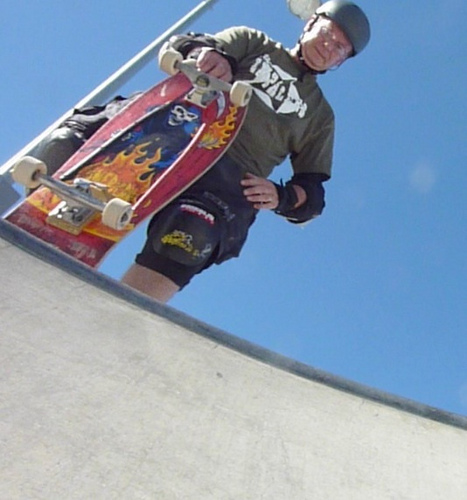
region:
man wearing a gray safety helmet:
[295, 0, 371, 75]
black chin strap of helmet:
[293, 12, 328, 72]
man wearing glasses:
[314, 23, 348, 59]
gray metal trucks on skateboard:
[176, 60, 230, 108]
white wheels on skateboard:
[229, 80, 252, 106]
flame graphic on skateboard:
[195, 102, 241, 150]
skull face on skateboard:
[167, 103, 198, 129]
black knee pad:
[149, 199, 224, 271]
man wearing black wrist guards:
[275, 178, 301, 214]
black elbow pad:
[290, 174, 327, 224]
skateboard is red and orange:
[33, 58, 242, 236]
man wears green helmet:
[313, 0, 367, 57]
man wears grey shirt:
[213, 19, 349, 201]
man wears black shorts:
[90, 77, 254, 297]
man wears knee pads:
[152, 181, 232, 279]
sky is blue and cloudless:
[342, 15, 466, 459]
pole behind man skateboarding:
[19, 1, 268, 149]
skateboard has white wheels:
[160, 48, 248, 118]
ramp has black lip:
[10, 216, 466, 410]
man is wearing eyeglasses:
[321, 12, 345, 75]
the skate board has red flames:
[95, 95, 241, 206]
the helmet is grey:
[329, 6, 379, 44]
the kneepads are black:
[171, 206, 233, 248]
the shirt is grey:
[251, 40, 335, 160]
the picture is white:
[257, 57, 318, 111]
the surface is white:
[53, 381, 240, 455]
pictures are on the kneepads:
[163, 227, 203, 249]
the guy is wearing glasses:
[300, 19, 358, 83]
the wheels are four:
[7, 55, 265, 235]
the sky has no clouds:
[379, 117, 427, 334]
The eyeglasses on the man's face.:
[318, 18, 351, 50]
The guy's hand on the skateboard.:
[194, 41, 237, 74]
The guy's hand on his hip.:
[244, 170, 278, 212]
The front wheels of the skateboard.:
[162, 48, 257, 110]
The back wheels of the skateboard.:
[19, 153, 143, 235]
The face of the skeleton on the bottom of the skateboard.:
[170, 99, 196, 123]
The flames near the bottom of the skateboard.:
[105, 136, 161, 201]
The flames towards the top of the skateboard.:
[203, 92, 236, 150]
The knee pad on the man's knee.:
[148, 189, 223, 261]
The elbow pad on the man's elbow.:
[295, 179, 330, 227]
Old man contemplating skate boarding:
[7, 4, 371, 318]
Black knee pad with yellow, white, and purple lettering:
[149, 196, 222, 269]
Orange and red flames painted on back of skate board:
[78, 134, 167, 199]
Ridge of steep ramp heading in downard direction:
[195, 310, 437, 476]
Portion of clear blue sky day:
[337, 187, 455, 317]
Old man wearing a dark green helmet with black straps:
[294, 1, 376, 81]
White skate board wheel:
[228, 76, 254, 107]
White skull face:
[159, 97, 201, 134]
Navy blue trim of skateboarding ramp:
[215, 320, 360, 380]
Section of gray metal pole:
[10, 0, 187, 96]